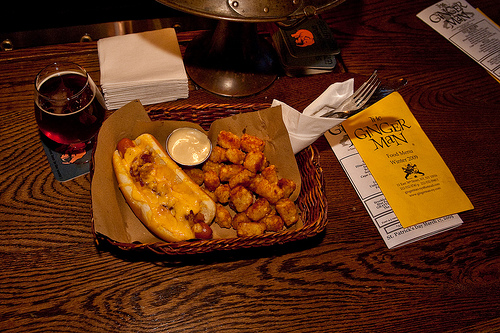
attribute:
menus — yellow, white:
[291, 88, 472, 253]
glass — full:
[34, 57, 108, 147]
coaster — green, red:
[277, 19, 340, 73]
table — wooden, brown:
[3, 1, 498, 331]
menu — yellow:
[344, 89, 482, 237]